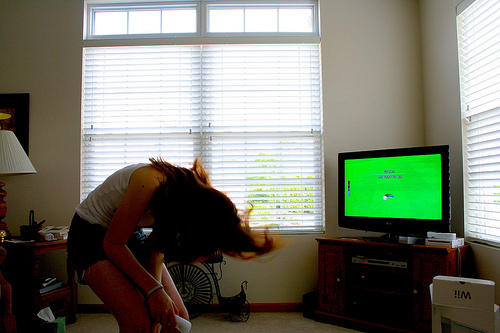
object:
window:
[78, 0, 325, 234]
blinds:
[75, 39, 327, 239]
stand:
[303, 236, 470, 333]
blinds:
[78, 0, 326, 233]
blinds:
[454, 0, 500, 244]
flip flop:
[331, 140, 461, 236]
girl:
[67, 164, 282, 310]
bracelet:
[130, 236, 183, 308]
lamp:
[0, 130, 38, 237]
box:
[406, 251, 484, 327]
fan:
[168, 265, 220, 316]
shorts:
[67, 212, 148, 285]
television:
[337, 144, 450, 245]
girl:
[65, 157, 287, 332]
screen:
[344, 153, 442, 221]